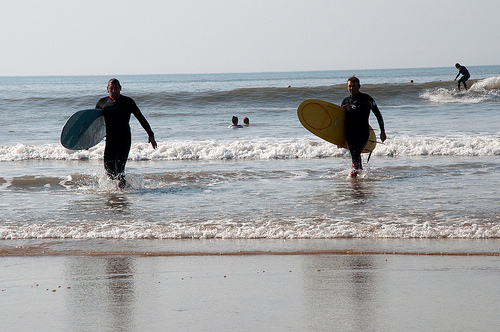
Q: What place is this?
A: It is an ocean.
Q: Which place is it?
A: It is an ocean.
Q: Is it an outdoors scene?
A: Yes, it is outdoors.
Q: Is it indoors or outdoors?
A: It is outdoors.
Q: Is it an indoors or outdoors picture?
A: It is outdoors.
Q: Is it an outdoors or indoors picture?
A: It is outdoors.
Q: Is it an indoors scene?
A: No, it is outdoors.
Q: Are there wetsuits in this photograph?
A: Yes, there is a wetsuit.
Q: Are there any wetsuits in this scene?
A: Yes, there is a wetsuit.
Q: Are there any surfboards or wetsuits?
A: Yes, there is a wetsuit.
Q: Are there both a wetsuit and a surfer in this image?
A: Yes, there are both a wetsuit and a surfer.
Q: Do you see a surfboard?
A: Yes, there is a surfboard.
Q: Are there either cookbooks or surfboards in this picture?
A: Yes, there is a surfboard.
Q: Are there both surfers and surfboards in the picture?
A: Yes, there are both a surfboard and a surfer.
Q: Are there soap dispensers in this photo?
A: No, there are no soap dispensers.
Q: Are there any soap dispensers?
A: No, there are no soap dispensers.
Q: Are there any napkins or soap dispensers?
A: No, there are no soap dispensers or napkins.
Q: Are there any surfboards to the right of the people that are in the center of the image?
A: Yes, there is a surfboard to the right of the people.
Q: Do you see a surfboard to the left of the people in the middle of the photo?
A: No, the surfboard is to the right of the people.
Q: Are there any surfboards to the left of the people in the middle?
A: No, the surfboard is to the right of the people.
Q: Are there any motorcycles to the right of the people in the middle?
A: No, there is a surfboard to the right of the people.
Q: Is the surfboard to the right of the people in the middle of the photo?
A: Yes, the surfboard is to the right of the people.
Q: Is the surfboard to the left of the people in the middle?
A: No, the surfboard is to the right of the people.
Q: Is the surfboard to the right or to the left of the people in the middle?
A: The surfboard is to the right of the people.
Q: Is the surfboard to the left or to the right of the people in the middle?
A: The surfboard is to the right of the people.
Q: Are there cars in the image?
A: No, there are no cars.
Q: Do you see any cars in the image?
A: No, there are no cars.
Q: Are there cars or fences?
A: No, there are no cars or fences.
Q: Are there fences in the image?
A: No, there are no fences.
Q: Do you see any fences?
A: No, there are no fences.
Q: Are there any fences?
A: No, there are no fences.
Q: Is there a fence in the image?
A: No, there are no fences.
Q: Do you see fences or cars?
A: No, there are no fences or cars.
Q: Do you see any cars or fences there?
A: No, there are no fences or cars.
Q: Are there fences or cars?
A: No, there are no fences or cars.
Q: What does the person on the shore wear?
A: The person wears a wetsuit.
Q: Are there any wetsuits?
A: Yes, there is a wetsuit.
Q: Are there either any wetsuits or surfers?
A: Yes, there is a wetsuit.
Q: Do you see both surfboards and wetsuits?
A: Yes, there are both a wetsuit and a surfboard.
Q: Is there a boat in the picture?
A: No, there are no boats.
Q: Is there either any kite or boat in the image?
A: No, there are no boats or kites.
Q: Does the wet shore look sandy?
A: Yes, the shore is sandy.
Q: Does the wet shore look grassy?
A: No, the shore is sandy.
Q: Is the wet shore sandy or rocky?
A: The shore is sandy.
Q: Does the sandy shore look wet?
A: Yes, the sea shore is wet.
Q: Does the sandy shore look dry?
A: No, the shore is wet.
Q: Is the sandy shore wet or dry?
A: The shore is wet.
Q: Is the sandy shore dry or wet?
A: The shore is wet.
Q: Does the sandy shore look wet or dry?
A: The shore is wet.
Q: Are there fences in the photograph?
A: No, there are no fences.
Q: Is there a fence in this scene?
A: No, there are no fences.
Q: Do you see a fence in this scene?
A: No, there are no fences.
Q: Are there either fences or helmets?
A: No, there are no fences or helmets.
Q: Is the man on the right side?
A: Yes, the man is on the right of the image.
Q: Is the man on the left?
A: No, the man is on the right of the image.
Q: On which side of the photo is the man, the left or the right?
A: The man is on the right of the image.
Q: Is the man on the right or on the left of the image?
A: The man is on the right of the image.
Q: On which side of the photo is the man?
A: The man is on the right of the image.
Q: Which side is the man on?
A: The man is on the right of the image.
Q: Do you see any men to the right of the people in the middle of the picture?
A: Yes, there is a man to the right of the people.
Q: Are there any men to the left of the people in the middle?
A: No, the man is to the right of the people.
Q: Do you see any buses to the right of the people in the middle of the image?
A: No, there is a man to the right of the people.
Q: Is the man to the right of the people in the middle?
A: Yes, the man is to the right of the people.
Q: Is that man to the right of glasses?
A: No, the man is to the right of the people.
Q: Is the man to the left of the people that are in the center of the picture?
A: No, the man is to the right of the people.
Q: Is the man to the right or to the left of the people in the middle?
A: The man is to the right of the people.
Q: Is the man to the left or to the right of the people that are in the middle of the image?
A: The man is to the right of the people.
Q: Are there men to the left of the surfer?
A: Yes, there is a man to the left of the surfer.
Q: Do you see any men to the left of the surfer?
A: Yes, there is a man to the left of the surfer.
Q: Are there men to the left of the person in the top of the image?
A: Yes, there is a man to the left of the surfer.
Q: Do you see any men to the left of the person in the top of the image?
A: Yes, there is a man to the left of the surfer.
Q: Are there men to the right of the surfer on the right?
A: No, the man is to the left of the surfer.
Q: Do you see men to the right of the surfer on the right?
A: No, the man is to the left of the surfer.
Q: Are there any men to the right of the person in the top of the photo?
A: No, the man is to the left of the surfer.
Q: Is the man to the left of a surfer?
A: Yes, the man is to the left of a surfer.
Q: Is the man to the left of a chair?
A: No, the man is to the left of a surfer.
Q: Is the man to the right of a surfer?
A: No, the man is to the left of a surfer.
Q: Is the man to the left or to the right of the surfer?
A: The man is to the left of the surfer.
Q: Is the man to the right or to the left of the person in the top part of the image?
A: The man is to the left of the surfer.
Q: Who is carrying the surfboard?
A: The man is carrying the surfboard.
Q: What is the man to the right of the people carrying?
A: The man is carrying a surfboard.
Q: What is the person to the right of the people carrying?
A: The man is carrying a surfboard.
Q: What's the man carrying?
A: The man is carrying a surfboard.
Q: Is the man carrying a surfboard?
A: Yes, the man is carrying a surfboard.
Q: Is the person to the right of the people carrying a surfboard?
A: Yes, the man is carrying a surfboard.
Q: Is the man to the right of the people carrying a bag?
A: No, the man is carrying a surfboard.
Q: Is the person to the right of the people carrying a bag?
A: No, the man is carrying a surfboard.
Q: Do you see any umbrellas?
A: No, there are no umbrellas.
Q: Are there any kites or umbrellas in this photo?
A: No, there are no umbrellas or kites.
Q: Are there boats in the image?
A: No, there are no boats.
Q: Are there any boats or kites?
A: No, there are no boats or kites.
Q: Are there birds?
A: No, there are no birds.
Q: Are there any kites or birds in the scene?
A: No, there are no birds or kites.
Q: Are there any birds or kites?
A: No, there are no birds or kites.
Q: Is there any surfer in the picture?
A: Yes, there is a surfer.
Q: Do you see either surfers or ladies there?
A: Yes, there is a surfer.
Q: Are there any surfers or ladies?
A: Yes, there is a surfer.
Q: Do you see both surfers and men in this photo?
A: Yes, there are both a surfer and a man.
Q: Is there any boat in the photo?
A: No, there are no boats.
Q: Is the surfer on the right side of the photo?
A: Yes, the surfer is on the right of the image.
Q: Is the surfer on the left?
A: No, the surfer is on the right of the image.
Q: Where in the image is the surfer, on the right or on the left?
A: The surfer is on the right of the image.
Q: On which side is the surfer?
A: The surfer is on the right of the image.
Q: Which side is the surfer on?
A: The surfer is on the right of the image.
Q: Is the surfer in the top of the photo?
A: Yes, the surfer is in the top of the image.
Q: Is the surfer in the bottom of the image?
A: No, the surfer is in the top of the image.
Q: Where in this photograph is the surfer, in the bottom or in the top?
A: The surfer is in the top of the image.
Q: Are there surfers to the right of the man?
A: Yes, there is a surfer to the right of the man.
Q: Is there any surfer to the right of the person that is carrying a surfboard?
A: Yes, there is a surfer to the right of the man.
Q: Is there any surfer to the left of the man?
A: No, the surfer is to the right of the man.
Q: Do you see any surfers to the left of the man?
A: No, the surfer is to the right of the man.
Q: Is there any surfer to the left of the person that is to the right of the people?
A: No, the surfer is to the right of the man.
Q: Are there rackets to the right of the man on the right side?
A: No, there is a surfer to the right of the man.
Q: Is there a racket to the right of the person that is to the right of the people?
A: No, there is a surfer to the right of the man.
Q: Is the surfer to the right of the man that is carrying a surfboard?
A: Yes, the surfer is to the right of the man.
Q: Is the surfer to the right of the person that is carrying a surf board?
A: Yes, the surfer is to the right of the man.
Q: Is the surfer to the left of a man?
A: No, the surfer is to the right of a man.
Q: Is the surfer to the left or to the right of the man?
A: The surfer is to the right of the man.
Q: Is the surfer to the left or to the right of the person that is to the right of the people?
A: The surfer is to the right of the man.